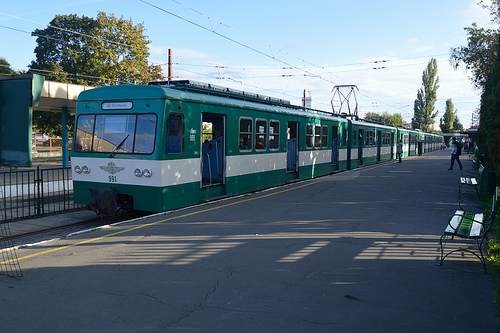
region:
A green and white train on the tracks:
[40, 42, 410, 188]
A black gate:
[0, 132, 75, 214]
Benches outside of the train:
[440, 155, 496, 271]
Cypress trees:
[400, 35, 460, 150]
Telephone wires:
[135, 22, 440, 87]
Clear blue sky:
[130, 0, 395, 43]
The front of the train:
[76, 102, 181, 167]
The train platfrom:
[95, 210, 450, 311]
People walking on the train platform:
[428, 117, 461, 179]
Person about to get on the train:
[390, 134, 418, 179]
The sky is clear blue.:
[147, 3, 475, 85]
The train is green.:
[62, 77, 465, 211]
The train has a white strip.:
[72, 133, 466, 197]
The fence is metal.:
[1, 169, 71, 211]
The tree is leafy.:
[38, 8, 146, 98]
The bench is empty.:
[442, 183, 493, 263]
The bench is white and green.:
[440, 188, 492, 263]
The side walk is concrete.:
[2, 143, 497, 318]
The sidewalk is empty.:
[27, 131, 487, 331]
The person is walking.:
[440, 128, 471, 164]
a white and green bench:
[422, 161, 498, 278]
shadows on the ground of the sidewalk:
[181, 200, 383, 312]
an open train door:
[188, 101, 243, 213]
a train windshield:
[53, 92, 164, 169]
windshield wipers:
[85, 127, 140, 178]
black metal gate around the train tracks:
[0, 160, 83, 210]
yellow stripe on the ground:
[35, 210, 137, 272]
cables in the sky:
[282, 39, 452, 85]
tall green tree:
[387, 53, 447, 148]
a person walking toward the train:
[422, 131, 472, 201]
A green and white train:
[38, 90, 410, 225]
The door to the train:
[186, 107, 238, 197]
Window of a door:
[60, 102, 174, 157]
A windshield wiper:
[104, 133, 134, 158]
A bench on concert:
[431, 197, 497, 277]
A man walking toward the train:
[440, 133, 472, 177]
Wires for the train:
[221, 47, 410, 93]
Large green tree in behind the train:
[26, 16, 179, 75]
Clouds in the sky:
[232, 0, 457, 89]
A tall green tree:
[404, 50, 443, 129]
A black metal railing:
[5, 155, 65, 225]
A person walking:
[436, 130, 463, 166]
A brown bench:
[427, 191, 497, 267]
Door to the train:
[185, 105, 248, 196]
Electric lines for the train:
[277, 40, 413, 87]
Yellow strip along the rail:
[57, 198, 243, 250]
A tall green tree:
[397, 48, 454, 123]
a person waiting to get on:
[388, 135, 413, 165]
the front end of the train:
[73, 87, 174, 211]